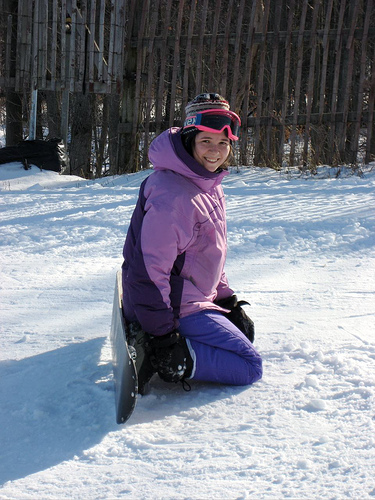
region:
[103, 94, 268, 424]
a girl kneeling in snow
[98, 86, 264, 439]
a girl on a snowboard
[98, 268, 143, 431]
a long black snowboard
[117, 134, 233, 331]
a purple and pink winter coat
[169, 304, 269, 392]
a pair of blue snow pants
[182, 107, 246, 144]
pink protective eyewear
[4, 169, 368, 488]
a field of snow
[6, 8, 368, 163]
a brown wood fence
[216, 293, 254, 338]
a brown snow glove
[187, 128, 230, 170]
a girl's smiling face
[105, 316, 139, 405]
the bottom of a snowboard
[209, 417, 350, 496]
The white snow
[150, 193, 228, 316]
Women is wearing a jacket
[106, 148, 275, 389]
Women is sitting on the snow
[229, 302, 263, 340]
women is wearing gloves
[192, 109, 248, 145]
black and pink snow goggles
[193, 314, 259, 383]
women is wearing pants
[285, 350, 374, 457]
The snow is white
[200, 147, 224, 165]
the women is smiling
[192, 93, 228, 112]
Women is wearing a beanie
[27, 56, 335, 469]
Young person sitting in snow.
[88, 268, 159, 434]
A black snowboard.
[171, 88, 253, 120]
A multi colored toboggan.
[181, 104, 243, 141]
A pair of pink goggles.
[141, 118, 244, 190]
Hood on winter jacket.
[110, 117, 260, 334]
A long sleeve jacket.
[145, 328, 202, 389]
Glove on right hand.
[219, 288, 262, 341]
Glove on left hand.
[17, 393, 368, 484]
Tracks in the snow.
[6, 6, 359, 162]
A wood slat fence.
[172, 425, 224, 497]
the snow is white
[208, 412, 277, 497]
the snow is white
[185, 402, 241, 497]
the snow is white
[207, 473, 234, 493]
the snow is white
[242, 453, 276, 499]
the snow is white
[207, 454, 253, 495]
the snow is white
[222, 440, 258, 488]
the snow is white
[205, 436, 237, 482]
the snow is white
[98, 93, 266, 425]
Young girl kneeling in snow with snowboard on feet.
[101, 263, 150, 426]
Snowboard attached to girl's feet.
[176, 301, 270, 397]
Young girl dressed in lavender pants.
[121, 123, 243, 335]
Young girl dressed in lavender and purple jacket with hood.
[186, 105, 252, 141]
Young girl wearing pink goggles.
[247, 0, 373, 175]
Old weathered wood fence in background.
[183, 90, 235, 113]
Young girl wearing wool cap on head.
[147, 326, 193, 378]
Young girl wearing black glove on hand.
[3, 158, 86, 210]
Snow piled up against fence.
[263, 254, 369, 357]
Ski tracks in white snow.